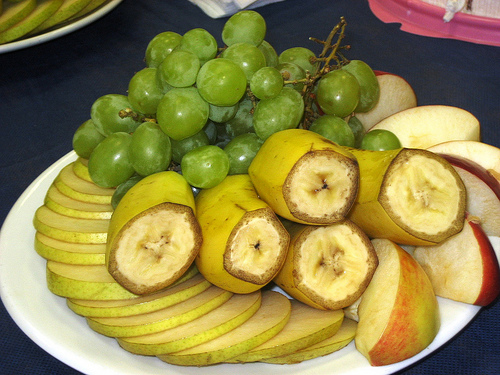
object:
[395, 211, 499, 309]
apple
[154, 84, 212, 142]
grapes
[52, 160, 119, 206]
apples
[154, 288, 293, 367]
pear slices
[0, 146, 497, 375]
plate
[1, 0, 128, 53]
plate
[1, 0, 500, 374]
table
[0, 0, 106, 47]
fruit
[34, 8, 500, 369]
fruit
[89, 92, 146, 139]
green grapes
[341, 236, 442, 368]
slice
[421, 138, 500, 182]
slice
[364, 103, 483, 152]
slice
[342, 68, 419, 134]
slice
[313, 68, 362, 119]
green grape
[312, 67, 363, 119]
grape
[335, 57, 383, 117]
grape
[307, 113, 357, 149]
grape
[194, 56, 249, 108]
grape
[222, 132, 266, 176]
grape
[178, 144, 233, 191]
grape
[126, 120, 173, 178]
grape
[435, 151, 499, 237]
apple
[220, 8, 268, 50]
grapes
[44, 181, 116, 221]
fruit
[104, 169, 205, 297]
banana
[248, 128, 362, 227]
banana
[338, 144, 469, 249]
banana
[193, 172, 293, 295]
banana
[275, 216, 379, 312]
banana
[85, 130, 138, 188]
grape